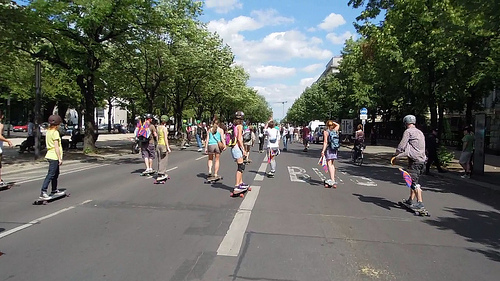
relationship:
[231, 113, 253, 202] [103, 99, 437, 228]
person on road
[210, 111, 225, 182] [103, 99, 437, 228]
person on road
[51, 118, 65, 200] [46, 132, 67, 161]
person wearing shirt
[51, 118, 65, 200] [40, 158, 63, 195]
person wearing jeans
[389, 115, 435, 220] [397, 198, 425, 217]
person riding skateboard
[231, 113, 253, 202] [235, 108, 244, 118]
person wearing helmet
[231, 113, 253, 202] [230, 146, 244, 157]
person wearing shorts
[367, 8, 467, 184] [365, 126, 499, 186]
tree on sidewalk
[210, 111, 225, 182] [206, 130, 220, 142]
person wearing shirt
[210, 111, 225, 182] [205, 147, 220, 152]
person wearing shorts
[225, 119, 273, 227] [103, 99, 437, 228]
line on road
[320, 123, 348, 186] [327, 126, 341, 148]
person wearing backpack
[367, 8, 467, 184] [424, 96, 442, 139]
tree has trunk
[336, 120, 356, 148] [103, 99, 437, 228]
sign on road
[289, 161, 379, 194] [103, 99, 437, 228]
word on road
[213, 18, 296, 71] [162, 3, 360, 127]
clouds in sky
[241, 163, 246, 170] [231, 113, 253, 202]
pads on person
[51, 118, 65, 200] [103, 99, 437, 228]
person on road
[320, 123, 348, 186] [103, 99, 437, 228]
person on road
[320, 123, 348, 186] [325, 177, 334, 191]
person on skateboard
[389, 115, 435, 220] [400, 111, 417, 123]
person wearing helmet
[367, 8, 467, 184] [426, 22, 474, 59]
tree with leaves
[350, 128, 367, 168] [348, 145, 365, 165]
person riding bike